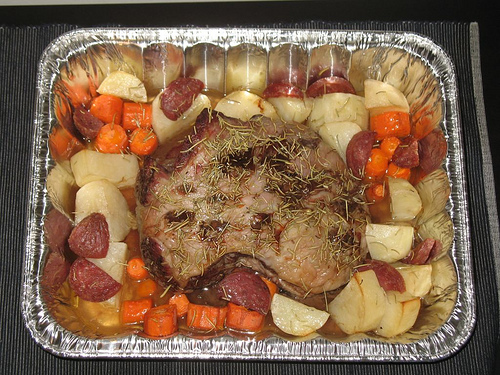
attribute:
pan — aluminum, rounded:
[38, 37, 112, 82]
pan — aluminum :
[37, 40, 494, 357]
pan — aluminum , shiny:
[22, 29, 474, 360]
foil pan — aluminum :
[18, 39, 485, 354]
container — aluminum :
[60, 33, 439, 271]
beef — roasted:
[165, 135, 357, 288]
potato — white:
[270, 293, 330, 336]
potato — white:
[334, 259, 415, 339]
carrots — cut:
[89, 96, 160, 156]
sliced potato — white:
[53, 153, 142, 188]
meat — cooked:
[140, 111, 362, 291]